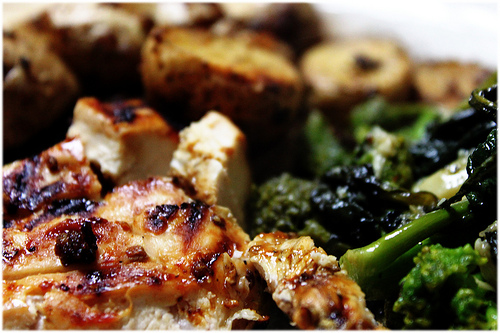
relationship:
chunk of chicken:
[63, 96, 178, 200] [1, 99, 387, 332]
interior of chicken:
[107, 298, 196, 327] [77, 87, 252, 204]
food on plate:
[3, 2, 498, 331] [29, 2, 499, 73]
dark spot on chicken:
[53, 221, 98, 267] [1, 99, 387, 332]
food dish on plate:
[74, 244, 271, 333] [7, 3, 497, 330]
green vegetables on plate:
[249, 69, 497, 330] [7, 3, 497, 330]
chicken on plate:
[1, 99, 387, 332] [7, 3, 497, 330]